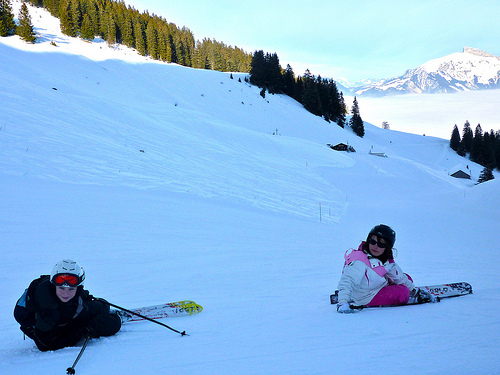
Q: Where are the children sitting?
A: On the ground.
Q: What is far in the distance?
A: A snow covered mountain.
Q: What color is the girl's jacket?
A: Pink and white.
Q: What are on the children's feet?
A: Skis.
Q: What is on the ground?
A: Snow.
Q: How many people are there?
A: Two.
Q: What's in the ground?
A: Snow.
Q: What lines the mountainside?
A: Trees.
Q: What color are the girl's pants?
A: Pink.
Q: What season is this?
A: Winter.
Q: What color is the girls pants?
A: Pink.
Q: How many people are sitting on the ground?
A: 2.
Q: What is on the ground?
A: Snow.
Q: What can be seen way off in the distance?
A: Snow capped mountains.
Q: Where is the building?
A: Down the hill.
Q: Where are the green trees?
A: To the left.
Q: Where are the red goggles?
A: On the person's white helmet.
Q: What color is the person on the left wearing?
A: Black.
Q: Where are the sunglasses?
A: On the girls' face.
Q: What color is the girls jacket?
A: Pink and white.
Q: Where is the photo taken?
A: On a ski slope.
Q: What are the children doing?
A: Sitting on the snow.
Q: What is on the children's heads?
A: Helmets.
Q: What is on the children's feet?
A: Skis.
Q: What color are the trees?
A: Green.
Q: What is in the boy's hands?
A: Trekking poles.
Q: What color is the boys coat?
A: Black.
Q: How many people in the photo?
A: Two.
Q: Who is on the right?
A: A girl.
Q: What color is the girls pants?
A: Pink.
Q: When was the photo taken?
A: Day time.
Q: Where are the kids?
A: The mountain.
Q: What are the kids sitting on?
A: Snow.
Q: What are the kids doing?
A: Sitting.